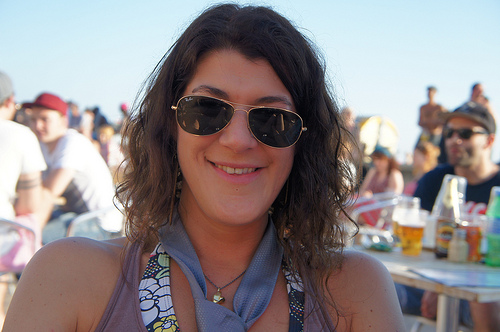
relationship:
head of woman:
[211, 59, 278, 96] [41, 4, 381, 329]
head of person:
[443, 110, 490, 178] [411, 98, 499, 215]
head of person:
[25, 99, 65, 137] [41, 113, 121, 224]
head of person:
[1, 77, 22, 116] [2, 72, 52, 261]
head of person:
[425, 86, 438, 105] [422, 88, 442, 140]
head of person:
[367, 144, 403, 174] [363, 141, 399, 241]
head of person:
[211, 59, 278, 96] [363, 141, 399, 241]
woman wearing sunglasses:
[41, 4, 381, 329] [179, 100, 221, 122]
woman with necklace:
[41, 4, 381, 329] [211, 281, 228, 299]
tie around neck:
[198, 306, 242, 331] [191, 222, 264, 255]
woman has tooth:
[41, 4, 381, 329] [226, 167, 237, 175]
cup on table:
[399, 214, 419, 252] [408, 258, 492, 298]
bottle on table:
[486, 190, 499, 260] [408, 258, 492, 298]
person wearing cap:
[41, 113, 121, 224] [32, 96, 64, 109]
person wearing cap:
[411, 98, 499, 215] [460, 100, 486, 122]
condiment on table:
[450, 229, 462, 258] [408, 258, 492, 298]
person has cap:
[41, 113, 121, 224] [32, 96, 64, 109]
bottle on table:
[442, 186, 451, 254] [408, 258, 492, 298]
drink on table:
[464, 223, 481, 263] [408, 258, 492, 298]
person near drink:
[411, 98, 499, 215] [464, 223, 481, 263]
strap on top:
[119, 253, 136, 283] [113, 300, 141, 329]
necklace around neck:
[211, 281, 228, 299] [191, 222, 264, 255]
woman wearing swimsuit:
[41, 4, 381, 329] [143, 268, 169, 326]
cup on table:
[398, 210, 424, 255] [408, 258, 492, 298]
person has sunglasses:
[411, 98, 499, 215] [445, 127, 462, 135]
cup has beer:
[399, 214, 419, 252] [402, 225, 425, 232]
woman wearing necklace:
[41, 4, 381, 329] [211, 281, 228, 299]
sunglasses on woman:
[179, 100, 221, 122] [41, 4, 381, 329]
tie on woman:
[198, 306, 242, 331] [41, 4, 381, 329]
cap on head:
[32, 96, 64, 109] [25, 99, 65, 137]